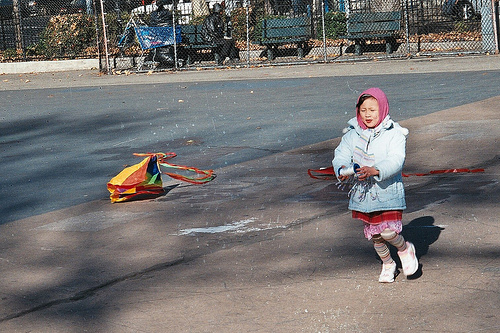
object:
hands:
[356, 166, 372, 181]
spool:
[338, 164, 359, 177]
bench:
[262, 17, 313, 59]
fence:
[0, 0, 499, 75]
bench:
[348, 11, 400, 53]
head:
[355, 88, 389, 130]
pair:
[377, 241, 419, 282]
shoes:
[378, 262, 399, 282]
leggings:
[373, 234, 392, 262]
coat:
[330, 117, 409, 212]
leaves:
[148, 118, 194, 143]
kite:
[106, 152, 215, 203]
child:
[331, 88, 419, 284]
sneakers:
[398, 242, 418, 276]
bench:
[182, 25, 222, 66]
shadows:
[0, 111, 499, 332]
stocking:
[381, 228, 405, 251]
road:
[0, 57, 500, 333]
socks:
[371, 236, 393, 263]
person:
[199, 3, 240, 65]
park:
[0, 0, 500, 333]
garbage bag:
[147, 8, 181, 27]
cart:
[133, 26, 180, 63]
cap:
[355, 87, 390, 129]